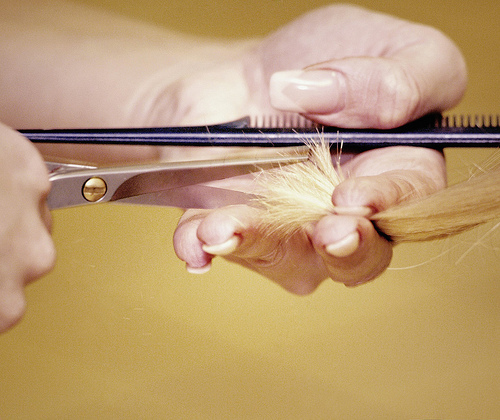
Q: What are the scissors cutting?
A: Hair.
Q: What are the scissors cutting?
A: Hair.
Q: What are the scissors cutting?
A: Hair.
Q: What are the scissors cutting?
A: Hair.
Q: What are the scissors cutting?
A: Hair.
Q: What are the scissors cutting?
A: Hair.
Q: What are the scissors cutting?
A: Hair.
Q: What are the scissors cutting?
A: Hair.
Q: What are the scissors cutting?
A: Hair.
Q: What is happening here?
A: Someone is getting a haircut.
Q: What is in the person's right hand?
A: Scissors.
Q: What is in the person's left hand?
A: A comb and strands of hair.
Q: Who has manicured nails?
A: The person cutting hair.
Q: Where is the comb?
A: In the person's hand.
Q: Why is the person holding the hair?
A: To better cut it.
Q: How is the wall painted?
A: Yellow.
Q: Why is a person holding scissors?
A: To cut someone's hair.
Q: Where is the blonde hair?
A: Between someone's fingers.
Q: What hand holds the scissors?
A: Right.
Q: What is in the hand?
A: A lock of hair.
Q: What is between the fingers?
A: A comb.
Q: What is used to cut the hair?
A: Scissors.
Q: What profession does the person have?
A: Hair dresser.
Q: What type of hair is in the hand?
A: Blonde.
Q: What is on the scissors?
A: A gold screw.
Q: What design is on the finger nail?
A: French tip.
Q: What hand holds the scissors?
A: The right.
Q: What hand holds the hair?
A: The left.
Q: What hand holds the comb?
A: The left.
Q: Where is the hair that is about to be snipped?
A: Between two fingers.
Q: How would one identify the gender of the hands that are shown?
A: Female.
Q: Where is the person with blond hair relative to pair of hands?
A: To the right.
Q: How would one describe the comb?
A: Black rat tail comb.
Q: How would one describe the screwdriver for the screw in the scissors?
A: Flat head screwdriver.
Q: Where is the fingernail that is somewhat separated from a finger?
A: Pinkie of left hand.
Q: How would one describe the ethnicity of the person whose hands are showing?
A: Caucasian.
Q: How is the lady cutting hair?
A: With scissors.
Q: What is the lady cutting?
A: Hair.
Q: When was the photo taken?
A: Daytime.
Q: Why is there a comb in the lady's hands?
A: To comb the hair.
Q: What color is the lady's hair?
A: Blonde.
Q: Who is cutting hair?
A: A lady.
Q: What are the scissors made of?
A: Metal.